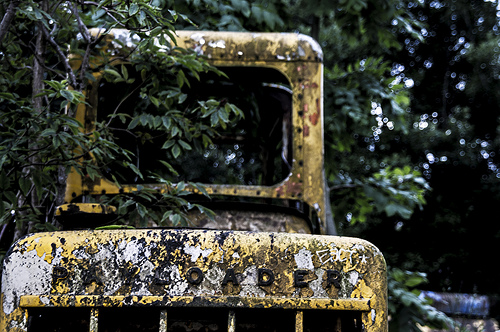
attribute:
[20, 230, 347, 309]
writing — black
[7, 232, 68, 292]
paint — peeled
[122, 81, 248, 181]
tree — green, leafy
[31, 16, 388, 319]
vehicle — yellow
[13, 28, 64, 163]
branch — brown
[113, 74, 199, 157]
tree — green, leafy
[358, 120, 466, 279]
bush — filled, leafy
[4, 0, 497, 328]
forest — black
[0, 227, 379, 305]
paint — faded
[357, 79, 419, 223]
leaves — shiny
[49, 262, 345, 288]
letters — black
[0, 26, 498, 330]
payloader — abandoned, yellow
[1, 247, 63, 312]
area — white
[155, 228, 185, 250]
marks — black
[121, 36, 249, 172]
leaves — green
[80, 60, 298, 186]
window opening — glassless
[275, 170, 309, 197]
area — rusted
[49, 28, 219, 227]
leaves — green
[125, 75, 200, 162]
leaves — green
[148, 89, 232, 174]
leaves — green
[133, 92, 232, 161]
leaves — green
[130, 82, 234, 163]
leaves — green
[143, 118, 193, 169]
leaves — green